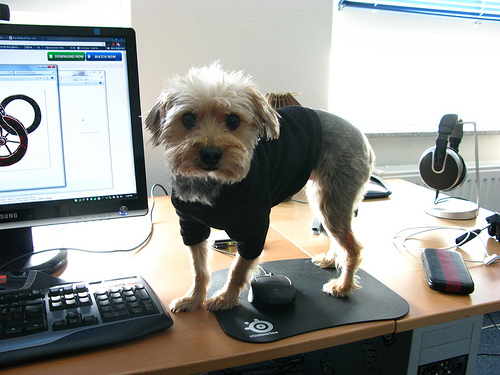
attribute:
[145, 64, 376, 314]
dog — brown, grey, small, white, black, little, staring at camera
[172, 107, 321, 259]
shirt — black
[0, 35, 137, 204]
computer screen — lit up, turned on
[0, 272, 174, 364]
keyboard — black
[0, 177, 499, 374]
desk — brown, grey, large, wooden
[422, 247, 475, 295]
phone case — striped, red, black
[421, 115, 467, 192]
headphones — black, gray, silver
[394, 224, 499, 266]
cord — long, white, wrapped up, rolled up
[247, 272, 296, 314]
computer mouse — black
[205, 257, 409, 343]
mouse pad — black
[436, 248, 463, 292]
stripe — maroon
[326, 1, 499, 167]
window — white, with daylight, large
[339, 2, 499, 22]
blinds — raised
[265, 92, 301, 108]
lampshade — top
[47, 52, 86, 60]
button — green, download now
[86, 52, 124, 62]
button — blue, power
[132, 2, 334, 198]
wall — white